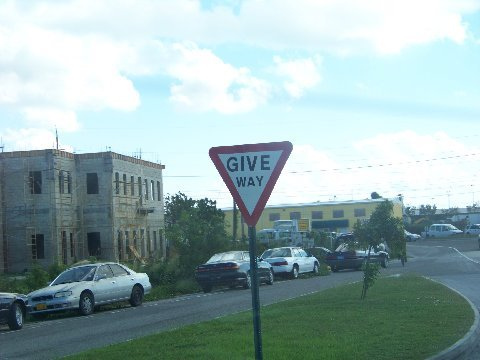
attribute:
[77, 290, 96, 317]
tire — black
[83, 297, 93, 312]
hubcap — silver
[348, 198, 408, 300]
tree — small, green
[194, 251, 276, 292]
car — black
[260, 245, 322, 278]
car — white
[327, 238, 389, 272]
car — black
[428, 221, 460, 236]
van — white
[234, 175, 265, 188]
letters — black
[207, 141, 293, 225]
sign — red, white, black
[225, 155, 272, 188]
instruction — Give Way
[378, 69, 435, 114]
sky — blue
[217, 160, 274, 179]
letters — black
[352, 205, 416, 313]
tree — green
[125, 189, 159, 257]
metal — yellow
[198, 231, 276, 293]
car — silver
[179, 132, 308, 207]
sign — yellow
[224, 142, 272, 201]
lettering — black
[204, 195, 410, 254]
yellow building — large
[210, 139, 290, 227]
triangular sign — white, red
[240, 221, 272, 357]
sign post — green, metal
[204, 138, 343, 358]
sign in the grass — in the grass